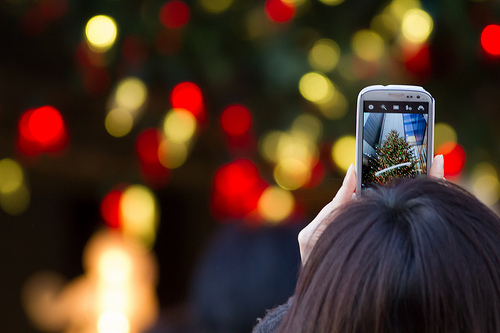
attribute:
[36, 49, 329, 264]
lights — red, yellow